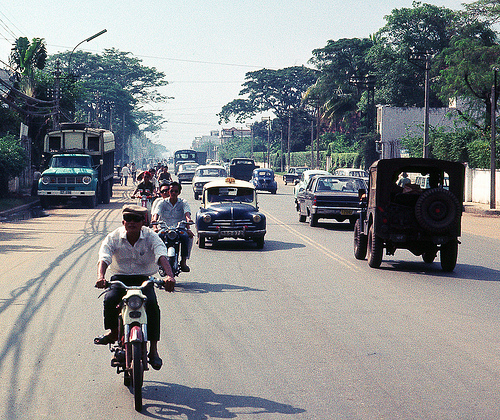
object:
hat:
[122, 204, 152, 227]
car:
[353, 158, 465, 273]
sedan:
[331, 168, 369, 178]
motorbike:
[94, 276, 181, 410]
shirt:
[153, 197, 191, 228]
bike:
[97, 279, 184, 410]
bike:
[149, 220, 195, 277]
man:
[150, 182, 193, 272]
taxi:
[195, 177, 267, 248]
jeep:
[354, 158, 464, 272]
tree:
[237, 64, 317, 173]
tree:
[429, 34, 500, 136]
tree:
[363, 0, 459, 107]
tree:
[0, 36, 46, 197]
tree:
[41, 47, 173, 131]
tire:
[131, 341, 142, 412]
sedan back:
[309, 175, 368, 227]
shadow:
[139, 380, 305, 420]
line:
[306, 241, 359, 273]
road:
[0, 332, 101, 417]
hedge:
[250, 151, 361, 166]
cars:
[194, 177, 265, 248]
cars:
[292, 170, 332, 203]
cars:
[224, 158, 260, 182]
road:
[262, 269, 500, 420]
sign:
[224, 177, 235, 184]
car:
[177, 163, 200, 184]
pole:
[423, 50, 429, 158]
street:
[2, 147, 495, 418]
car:
[294, 174, 368, 226]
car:
[249, 168, 277, 195]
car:
[192, 165, 228, 200]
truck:
[33, 123, 115, 209]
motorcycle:
[148, 220, 196, 276]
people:
[150, 182, 171, 223]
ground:
[0, 167, 499, 419]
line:
[267, 216, 365, 273]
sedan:
[283, 167, 310, 186]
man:
[95, 203, 175, 370]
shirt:
[95, 225, 168, 276]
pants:
[103, 275, 160, 342]